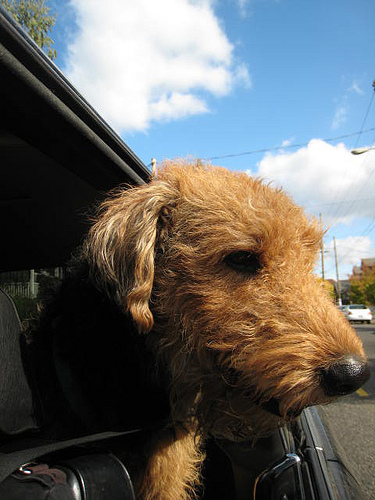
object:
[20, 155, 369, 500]
dog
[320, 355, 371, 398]
nose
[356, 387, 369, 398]
yellow line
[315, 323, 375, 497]
road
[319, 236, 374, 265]
clouds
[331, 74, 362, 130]
clouds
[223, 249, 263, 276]
eye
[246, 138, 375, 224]
cloud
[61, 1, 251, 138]
cloud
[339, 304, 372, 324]
car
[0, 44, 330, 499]
window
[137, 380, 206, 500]
leg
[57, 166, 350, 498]
dog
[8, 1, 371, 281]
sky